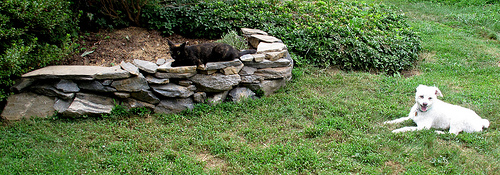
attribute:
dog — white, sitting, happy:
[388, 74, 493, 141]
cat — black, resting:
[162, 33, 266, 72]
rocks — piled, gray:
[58, 58, 288, 121]